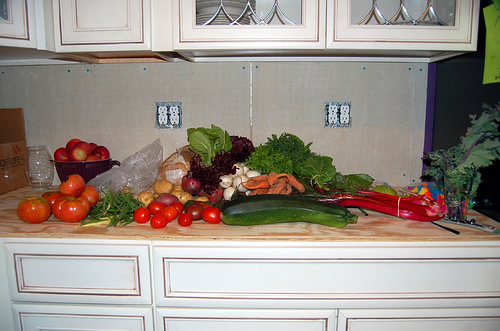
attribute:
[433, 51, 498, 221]
refrigerator — black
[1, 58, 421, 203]
wall — brown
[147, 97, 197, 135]
outlet — uncovered, electrical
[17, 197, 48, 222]
tomato — red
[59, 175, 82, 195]
tomato — red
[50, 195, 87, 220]
tomato — red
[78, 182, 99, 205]
tomato — red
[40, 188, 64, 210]
tomato — red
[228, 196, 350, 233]
cucumber — green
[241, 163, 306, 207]
carrots — orange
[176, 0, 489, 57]
cabinet doors — white, glass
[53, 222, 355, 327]
drawers — white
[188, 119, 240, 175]
spinach — fresh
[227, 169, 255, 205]
onions — mounded, white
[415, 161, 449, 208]
paper — green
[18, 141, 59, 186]
glass — empty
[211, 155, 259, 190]
garlic — white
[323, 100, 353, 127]
outlet — electrical, uncovered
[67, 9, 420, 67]
cupboard — white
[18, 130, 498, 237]
vegetables — piled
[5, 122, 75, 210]
jar — clear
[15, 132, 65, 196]
jar — glass